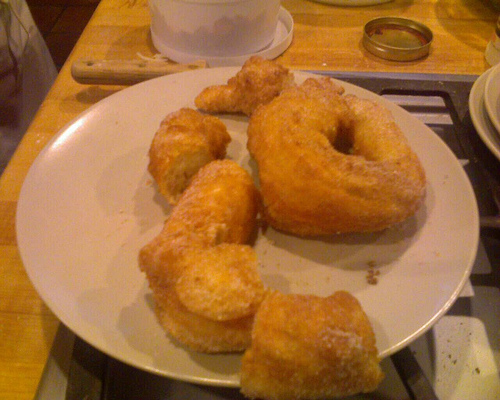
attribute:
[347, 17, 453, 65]
cap — gold, plastic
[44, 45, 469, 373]
plate — round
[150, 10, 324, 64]
container — white, plastic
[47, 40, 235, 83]
handle — wooden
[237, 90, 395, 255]
doughnut — round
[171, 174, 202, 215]
sugar — white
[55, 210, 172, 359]
plate — white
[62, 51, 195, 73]
handle — one, knife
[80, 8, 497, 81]
counter — one, wooden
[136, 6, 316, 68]
lid — plastic, white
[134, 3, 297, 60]
container — plastic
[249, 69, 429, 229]
donut — whole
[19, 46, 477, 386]
plate — white, one